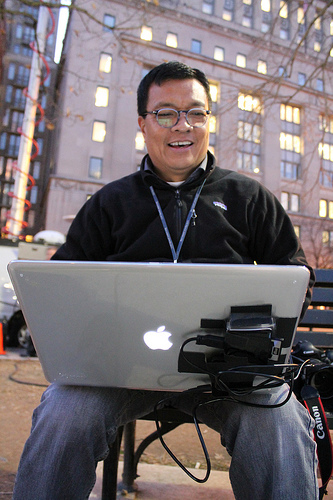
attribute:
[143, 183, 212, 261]
lanyard — blue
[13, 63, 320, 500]
man — smiling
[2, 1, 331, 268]
background — tall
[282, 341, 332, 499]
camera — cannon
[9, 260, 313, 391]
laptop — apple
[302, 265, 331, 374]
bench — black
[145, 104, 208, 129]
glasses — black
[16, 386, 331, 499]
jeans — denim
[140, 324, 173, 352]
logo — backlit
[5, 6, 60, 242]
cord — spiraled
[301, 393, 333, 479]
strap — red, black